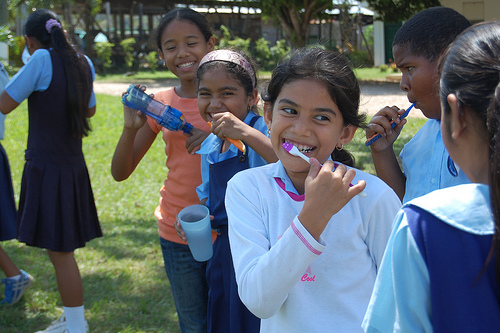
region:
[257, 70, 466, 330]
a girll brushing her teeth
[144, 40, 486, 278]
children brushing their teeth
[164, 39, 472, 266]
children hodling cups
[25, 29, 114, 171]
a girll with long hair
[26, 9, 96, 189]
a girl with her hari in ponyt ai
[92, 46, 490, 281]
children holding toothbrushes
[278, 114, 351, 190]
a purple and white toothrbushes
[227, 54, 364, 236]
girls that are smiling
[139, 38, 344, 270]
children that are smiling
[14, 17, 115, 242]
a girl wearing a jumper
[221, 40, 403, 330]
a kid brushing teeth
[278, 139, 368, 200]
a toothbrush the kid is using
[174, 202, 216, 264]
a cup the kid is holding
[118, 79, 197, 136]
a bottle the kid is holding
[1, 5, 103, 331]
a kid wearing school uniform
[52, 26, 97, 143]
long black hair of the girl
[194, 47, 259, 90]
a headband the kid is using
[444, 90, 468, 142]
an ear of the girl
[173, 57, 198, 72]
a smile of the girl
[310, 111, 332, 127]
an eye of the kid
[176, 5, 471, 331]
kids brushing their teeth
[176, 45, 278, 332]
girl wearing a headband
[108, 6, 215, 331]
girl holding a water bottle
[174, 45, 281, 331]
girl holding a glass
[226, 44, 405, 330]
girl holding a toothbrush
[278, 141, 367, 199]
white and purple toothbrush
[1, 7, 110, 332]
girl with a ponytail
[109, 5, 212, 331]
girl with orange shirt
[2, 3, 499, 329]
kids standing on the grass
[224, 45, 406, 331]
girl with white and pink sweater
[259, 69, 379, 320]
small child brushing teeth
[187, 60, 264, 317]
small child brushing teeth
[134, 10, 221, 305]
small child brushing teeth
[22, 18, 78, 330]
small child brushing teeth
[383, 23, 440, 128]
small child brushing teeth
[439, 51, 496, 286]
small child brushing teeth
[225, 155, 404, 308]
white sweater on child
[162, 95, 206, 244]
orange shirt on child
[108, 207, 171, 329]
grass growing below children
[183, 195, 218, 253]
blue cup in hand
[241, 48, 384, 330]
a girl in a pink shirt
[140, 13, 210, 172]
a girl in an orange shirt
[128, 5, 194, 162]
a girl holding a water bottle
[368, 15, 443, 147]
a boy holding a tooth brush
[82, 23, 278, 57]
bushes behind the kis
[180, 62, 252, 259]
a girl holding a cup of water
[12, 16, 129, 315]
a girl in a dress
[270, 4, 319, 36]
a tree behind the kids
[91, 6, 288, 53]
a fence behind the kids